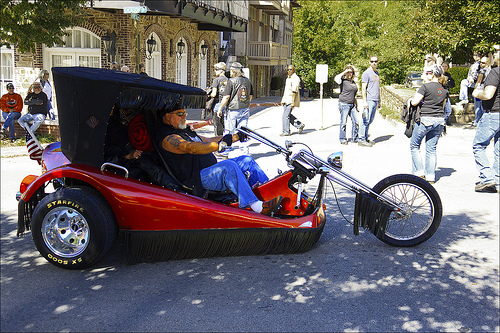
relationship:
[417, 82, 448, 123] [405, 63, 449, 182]
shirt on lady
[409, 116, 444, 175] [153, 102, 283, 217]
jeans worn by biker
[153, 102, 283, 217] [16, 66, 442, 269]
biker of bike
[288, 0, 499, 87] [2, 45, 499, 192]
trees behind crowd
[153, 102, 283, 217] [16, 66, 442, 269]
biker in bike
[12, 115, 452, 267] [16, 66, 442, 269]
motorcycle attached to bike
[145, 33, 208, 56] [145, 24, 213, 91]
lanterns by arches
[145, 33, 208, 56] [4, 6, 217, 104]
lanterns in wall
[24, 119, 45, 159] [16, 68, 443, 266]
us flag on back of cart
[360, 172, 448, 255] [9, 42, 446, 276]
front wheel on bike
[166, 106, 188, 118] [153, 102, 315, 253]
glasses on biker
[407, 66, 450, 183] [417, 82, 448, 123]
woman in shirt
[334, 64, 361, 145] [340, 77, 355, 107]
person in shirt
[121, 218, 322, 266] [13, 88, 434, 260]
fringe on bottom of chopper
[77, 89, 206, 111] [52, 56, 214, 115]
fringe on roof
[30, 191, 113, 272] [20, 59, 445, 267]
tire on back of chopper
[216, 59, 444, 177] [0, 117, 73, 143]
people sitting on wall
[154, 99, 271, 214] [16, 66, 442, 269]
man riding bike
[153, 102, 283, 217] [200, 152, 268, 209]
biker wearing jeans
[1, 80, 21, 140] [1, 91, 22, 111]
woman wearing shirt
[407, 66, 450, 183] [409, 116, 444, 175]
woman wearing jeans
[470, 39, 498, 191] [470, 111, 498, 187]
person wearing jeans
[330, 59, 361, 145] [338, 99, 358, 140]
person wearing jeans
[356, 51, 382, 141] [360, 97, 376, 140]
person wearing jeans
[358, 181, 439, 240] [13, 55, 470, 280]
wheel on chopper